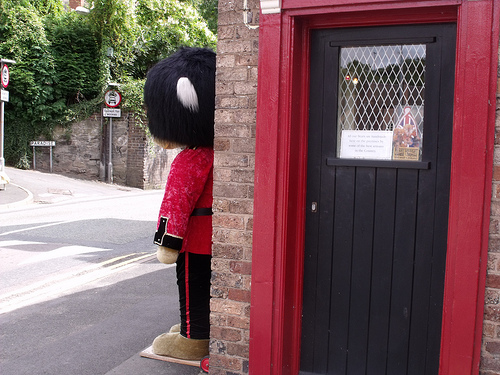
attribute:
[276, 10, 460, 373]
door — black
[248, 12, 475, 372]
door — black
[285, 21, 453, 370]
door — black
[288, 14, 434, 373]
door — black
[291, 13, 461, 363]
door — black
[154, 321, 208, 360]
feet — Large, brown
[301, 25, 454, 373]
door — black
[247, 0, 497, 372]
frame — red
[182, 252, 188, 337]
stripe — red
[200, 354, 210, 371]
wheel — red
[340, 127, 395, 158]
notice — white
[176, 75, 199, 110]
fur — white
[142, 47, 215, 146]
helmet — black, big, furry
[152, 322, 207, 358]
slippers — brown, furry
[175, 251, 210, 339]
pants — black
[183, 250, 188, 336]
stripe — red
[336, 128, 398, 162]
paper — white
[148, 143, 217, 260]
jacket — black, red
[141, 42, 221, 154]
hat — black, white, fluffy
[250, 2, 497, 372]
door — red, black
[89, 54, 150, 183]
sign — circular